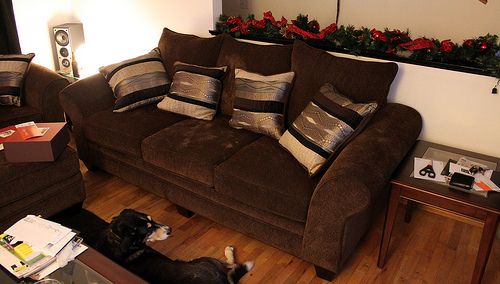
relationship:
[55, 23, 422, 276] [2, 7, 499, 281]
couch in living room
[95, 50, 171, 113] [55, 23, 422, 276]
accent pillows on couch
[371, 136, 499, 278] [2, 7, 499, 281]
end table in living room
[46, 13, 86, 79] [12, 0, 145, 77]
speaker in corner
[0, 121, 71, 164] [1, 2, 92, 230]
box on chair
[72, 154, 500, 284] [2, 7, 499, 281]
floor in living room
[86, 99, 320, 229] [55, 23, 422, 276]
cushions on couch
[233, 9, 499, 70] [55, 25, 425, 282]
planter box behind couch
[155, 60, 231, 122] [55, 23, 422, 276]
cushion on couch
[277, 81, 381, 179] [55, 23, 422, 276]
cushion on couch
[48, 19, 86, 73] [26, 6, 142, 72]
speaker in corner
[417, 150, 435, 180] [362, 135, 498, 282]
scissors on table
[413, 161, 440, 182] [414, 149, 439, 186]
handle of scissors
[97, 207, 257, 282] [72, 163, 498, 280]
dog on floor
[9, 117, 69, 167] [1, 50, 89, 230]
box on chair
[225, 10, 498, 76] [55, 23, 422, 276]
flowers behind couch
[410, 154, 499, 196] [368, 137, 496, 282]
papers on side table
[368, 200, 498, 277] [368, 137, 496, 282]
legs on side table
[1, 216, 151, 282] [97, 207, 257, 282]
table behind dog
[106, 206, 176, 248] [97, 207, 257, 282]
head of dog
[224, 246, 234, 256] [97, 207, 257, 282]
foot of dog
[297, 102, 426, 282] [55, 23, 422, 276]
arm of couch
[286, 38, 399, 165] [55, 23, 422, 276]
cushion on couch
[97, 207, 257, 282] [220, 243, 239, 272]
dog with foot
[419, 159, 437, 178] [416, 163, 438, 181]
scissors with handles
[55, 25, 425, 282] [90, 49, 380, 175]
couch with pillows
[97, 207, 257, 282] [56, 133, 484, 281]
dog on ground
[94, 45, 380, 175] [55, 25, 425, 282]
accent pillows on couch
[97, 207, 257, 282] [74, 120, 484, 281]
dog on floor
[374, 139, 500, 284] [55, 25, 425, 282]
end table beside couch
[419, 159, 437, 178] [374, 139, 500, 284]
scissors on end table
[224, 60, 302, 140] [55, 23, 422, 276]
cushion on couch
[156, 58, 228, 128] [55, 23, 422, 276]
cushion on couch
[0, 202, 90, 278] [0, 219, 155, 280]
books on top of table